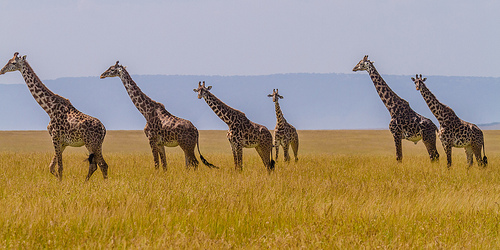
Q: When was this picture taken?
A: During the day.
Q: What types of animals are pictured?
A: Giraffes.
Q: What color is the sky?
A: Blue.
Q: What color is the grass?
A: Yellow.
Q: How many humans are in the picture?
A: Zero.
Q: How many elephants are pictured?
A: Zero.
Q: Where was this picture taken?
A: Savannah.